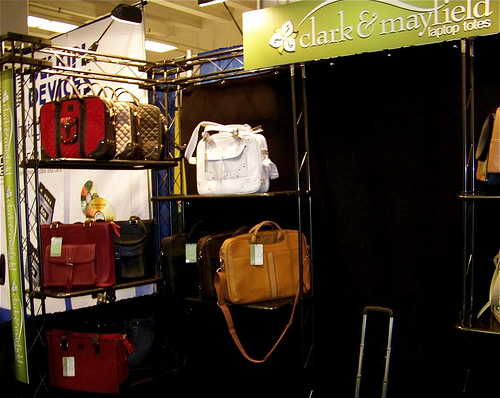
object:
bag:
[97, 82, 167, 162]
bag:
[329, 306, 434, 397]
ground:
[313, 160, 463, 250]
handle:
[358, 306, 394, 398]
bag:
[183, 120, 280, 196]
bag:
[38, 220, 120, 290]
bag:
[41, 78, 116, 159]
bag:
[46, 328, 136, 396]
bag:
[212, 220, 312, 364]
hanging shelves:
[6, 28, 322, 395]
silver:
[51, 42, 244, 83]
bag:
[196, 225, 249, 302]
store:
[10, 9, 498, 386]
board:
[57, 177, 133, 204]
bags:
[113, 87, 140, 162]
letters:
[296, 0, 500, 52]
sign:
[240, 1, 500, 61]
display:
[7, 18, 380, 390]